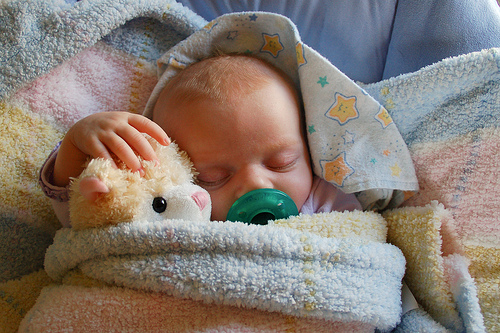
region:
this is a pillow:
[296, 5, 355, 41]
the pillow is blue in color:
[355, 14, 405, 49]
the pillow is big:
[342, 10, 416, 45]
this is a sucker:
[221, 191, 290, 218]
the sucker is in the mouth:
[214, 182, 308, 227]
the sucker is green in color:
[245, 197, 277, 213]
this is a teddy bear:
[72, 134, 210, 226]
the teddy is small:
[117, 177, 137, 212]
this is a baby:
[41, 25, 305, 237]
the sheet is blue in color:
[316, 94, 368, 148]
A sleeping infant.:
[1, 0, 499, 332]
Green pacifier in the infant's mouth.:
[226, 188, 299, 223]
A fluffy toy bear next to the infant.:
[69, 133, 211, 223]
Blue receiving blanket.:
[137, 11, 417, 193]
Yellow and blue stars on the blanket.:
[143, 13, 418, 195]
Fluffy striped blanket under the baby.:
[0, 1, 499, 332]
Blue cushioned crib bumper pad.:
[182, 1, 499, 84]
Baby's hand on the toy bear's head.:
[55, 109, 212, 229]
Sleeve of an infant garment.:
[35, 148, 67, 225]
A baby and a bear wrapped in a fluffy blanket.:
[19, 198, 482, 332]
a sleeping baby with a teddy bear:
[26, 17, 451, 274]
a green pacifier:
[223, 181, 297, 234]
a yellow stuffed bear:
[63, 132, 223, 245]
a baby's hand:
[22, 88, 174, 178]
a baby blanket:
[52, 224, 462, 314]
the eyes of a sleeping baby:
[187, 136, 321, 196]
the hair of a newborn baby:
[155, 48, 280, 112]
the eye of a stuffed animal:
[141, 188, 178, 219]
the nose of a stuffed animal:
[181, 183, 215, 217]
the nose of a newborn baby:
[232, 166, 276, 200]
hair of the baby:
[164, 53, 266, 101]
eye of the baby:
[272, 142, 299, 167]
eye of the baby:
[201, 148, 228, 197]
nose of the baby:
[230, 172, 269, 189]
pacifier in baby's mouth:
[230, 197, 288, 218]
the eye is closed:
[260, 153, 299, 172]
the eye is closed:
[197, 170, 233, 185]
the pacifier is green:
[262, 201, 292, 211]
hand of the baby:
[51, 100, 153, 166]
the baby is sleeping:
[165, 81, 317, 224]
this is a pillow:
[358, 19, 398, 51]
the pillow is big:
[352, 19, 379, 56]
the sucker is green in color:
[255, 192, 271, 204]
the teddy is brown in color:
[125, 177, 149, 197]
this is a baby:
[142, 62, 397, 332]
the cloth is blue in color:
[338, 117, 396, 160]